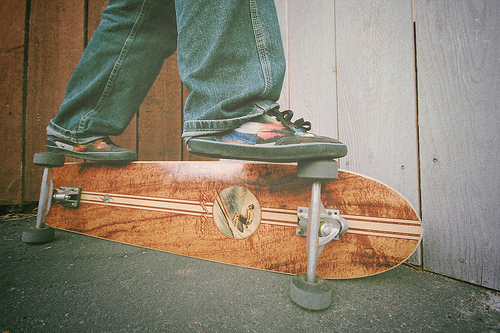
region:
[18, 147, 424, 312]
brown wooden skateboard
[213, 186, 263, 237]
round graphic printed on skateboard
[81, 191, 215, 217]
tan stripe printed on skateboard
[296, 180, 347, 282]
gray trucks attached to skateboard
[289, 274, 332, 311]
gray wheel below gray wheel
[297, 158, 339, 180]
wheel attached to truck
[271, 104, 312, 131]
black shoe lace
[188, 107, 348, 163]
colorful shoe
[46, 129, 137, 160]
colorful shoe behind shoe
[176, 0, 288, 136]
pant leg above shoe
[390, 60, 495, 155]
this is a wall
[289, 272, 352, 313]
this is the wheel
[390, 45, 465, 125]
the wall is wooden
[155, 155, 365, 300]
this is a skateboard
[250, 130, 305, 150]
this is a shoe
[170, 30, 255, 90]
this is a jeans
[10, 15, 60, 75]
the wall is brown in color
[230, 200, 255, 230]
this is a man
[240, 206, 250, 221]
the man is bare chested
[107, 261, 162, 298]
this is the floor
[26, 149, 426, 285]
bottom of wood skateboard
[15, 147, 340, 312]
gray wheels of the skateboard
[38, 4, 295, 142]
blue jeans of the skateboarder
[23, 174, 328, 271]
two axles of the skateboard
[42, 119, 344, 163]
shoes of the skateboarder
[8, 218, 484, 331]
pavement skateboarder is propped on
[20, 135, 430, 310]
skateboard turned on it's side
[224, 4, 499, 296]
gray wall behind skateboarder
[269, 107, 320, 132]
black shoelaces in shoe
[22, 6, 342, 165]
person standing on the skateboard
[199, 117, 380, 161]
tennis shoes on person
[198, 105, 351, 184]
person wearing tennis shoes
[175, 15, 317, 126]
blue jeans on person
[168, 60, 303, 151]
person wearing blue jeans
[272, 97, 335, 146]
black laces on shoe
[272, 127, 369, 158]
black bottom on shoe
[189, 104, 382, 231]
person standing on board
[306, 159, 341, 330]
black wheels on board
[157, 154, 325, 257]
brown bottom on board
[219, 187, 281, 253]
surf picture on board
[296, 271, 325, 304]
part of a wheel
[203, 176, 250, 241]
part of a circle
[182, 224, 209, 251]
part of a board